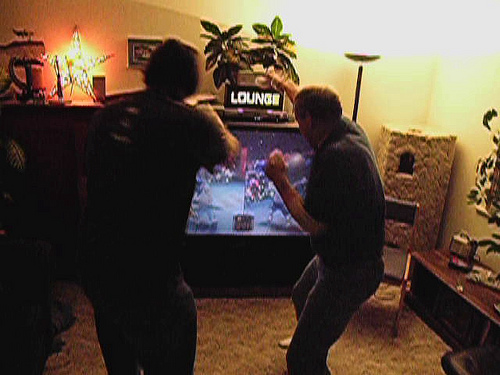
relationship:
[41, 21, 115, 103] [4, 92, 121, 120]
star on shelf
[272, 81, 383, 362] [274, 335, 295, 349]
man wearing sock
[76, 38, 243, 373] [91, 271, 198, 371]
man with pants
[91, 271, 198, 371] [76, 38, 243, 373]
pants on man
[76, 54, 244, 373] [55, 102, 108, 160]
man playing wii